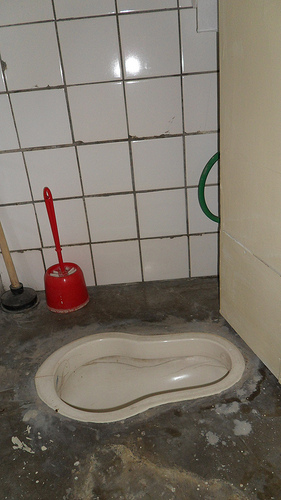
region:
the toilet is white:
[47, 336, 242, 415]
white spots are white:
[220, 402, 250, 443]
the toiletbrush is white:
[32, 191, 91, 306]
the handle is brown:
[3, 248, 23, 286]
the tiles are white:
[88, 144, 168, 217]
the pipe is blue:
[197, 162, 223, 219]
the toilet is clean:
[51, 335, 230, 408]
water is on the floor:
[93, 295, 188, 317]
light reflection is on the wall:
[104, 49, 141, 74]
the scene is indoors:
[2, 8, 278, 498]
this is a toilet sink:
[64, 347, 212, 406]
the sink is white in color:
[114, 370, 154, 394]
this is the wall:
[68, 26, 153, 157]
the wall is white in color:
[54, 97, 116, 162]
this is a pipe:
[198, 147, 217, 228]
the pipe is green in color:
[195, 163, 209, 214]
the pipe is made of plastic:
[194, 163, 214, 211]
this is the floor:
[125, 416, 243, 478]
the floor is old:
[173, 428, 229, 474]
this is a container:
[51, 281, 77, 306]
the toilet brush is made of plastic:
[40, 186, 88, 313]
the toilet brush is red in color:
[36, 185, 89, 312]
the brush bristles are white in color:
[49, 266, 74, 278]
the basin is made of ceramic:
[35, 330, 243, 421]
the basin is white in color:
[38, 333, 238, 426]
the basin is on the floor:
[36, 329, 247, 423]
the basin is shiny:
[40, 329, 241, 436]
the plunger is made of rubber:
[3, 281, 39, 311]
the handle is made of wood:
[2, 220, 19, 289]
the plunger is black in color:
[2, 282, 39, 312]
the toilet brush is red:
[37, 194, 84, 314]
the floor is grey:
[73, 446, 207, 487]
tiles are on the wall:
[88, 177, 148, 250]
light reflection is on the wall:
[112, 63, 149, 85]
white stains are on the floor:
[198, 406, 259, 448]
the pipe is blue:
[190, 171, 214, 210]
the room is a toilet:
[3, 4, 270, 496]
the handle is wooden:
[1, 250, 23, 284]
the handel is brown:
[1, 247, 20, 281]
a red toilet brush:
[30, 181, 91, 314]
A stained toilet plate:
[33, 335, 226, 402]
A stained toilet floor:
[187, 411, 269, 498]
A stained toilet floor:
[65, 432, 190, 492]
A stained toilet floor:
[3, 396, 64, 488]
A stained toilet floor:
[4, 317, 36, 378]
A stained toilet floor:
[105, 283, 223, 335]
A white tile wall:
[99, 157, 171, 242]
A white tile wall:
[15, 89, 109, 173]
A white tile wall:
[113, 72, 221, 164]